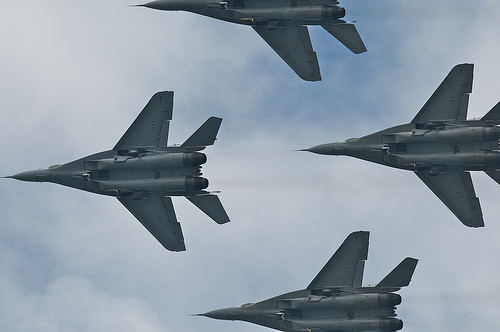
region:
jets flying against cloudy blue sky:
[11, 8, 496, 323]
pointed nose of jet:
[293, 100, 368, 165]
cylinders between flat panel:
[386, 122, 493, 168]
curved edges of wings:
[406, 58, 487, 230]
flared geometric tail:
[178, 110, 240, 225]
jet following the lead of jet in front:
[5, 64, 493, 251]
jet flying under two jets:
[3, 76, 493, 324]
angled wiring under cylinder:
[394, 125, 454, 147]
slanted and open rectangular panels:
[78, 152, 106, 194]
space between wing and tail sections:
[116, 85, 224, 150]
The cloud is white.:
[19, 13, 124, 92]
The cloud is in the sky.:
[16, 14, 118, 104]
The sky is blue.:
[271, 87, 315, 114]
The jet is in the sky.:
[0, 85, 233, 252]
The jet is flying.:
[194, 231, 434, 330]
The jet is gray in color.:
[128, 0, 392, 81]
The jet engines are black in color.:
[186, 149, 211, 189]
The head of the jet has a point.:
[292, 138, 341, 162]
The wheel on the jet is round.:
[75, 170, 95, 185]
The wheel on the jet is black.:
[77, 172, 94, 184]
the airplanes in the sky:
[0, 0, 496, 328]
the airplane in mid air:
[0, 0, 497, 330]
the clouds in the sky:
[0, 0, 497, 330]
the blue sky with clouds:
[0, 0, 499, 330]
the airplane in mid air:
[0, 90, 229, 252]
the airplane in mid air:
[289, 62, 497, 227]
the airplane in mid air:
[187, 230, 417, 328]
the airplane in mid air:
[125, 0, 366, 82]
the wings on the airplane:
[110, 90, 185, 250]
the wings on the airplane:
[409, 65, 484, 227]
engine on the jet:
[190, 152, 207, 163]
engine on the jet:
[195, 176, 210, 187]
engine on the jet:
[387, 291, 400, 304]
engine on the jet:
[335, 4, 348, 19]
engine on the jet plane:
[393, 315, 400, 325]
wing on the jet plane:
[410, 60, 481, 125]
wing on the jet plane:
[111, 91, 171, 147]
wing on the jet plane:
[305, 228, 366, 291]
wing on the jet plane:
[2, 86, 232, 249]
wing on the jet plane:
[290, 62, 499, 232]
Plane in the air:
[0, 75, 244, 264]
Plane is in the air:
[0, 80, 244, 254]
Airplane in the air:
[1, 81, 238, 256]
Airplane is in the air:
[0, 85, 237, 262]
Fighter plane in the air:
[0, 79, 235, 256]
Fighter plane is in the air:
[0, 87, 234, 257]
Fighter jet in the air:
[0, 84, 238, 260]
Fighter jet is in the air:
[3, 83, 240, 260]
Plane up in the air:
[0, 81, 237, 264]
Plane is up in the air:
[2, 76, 239, 262]